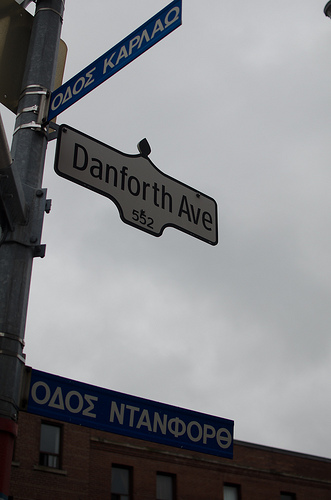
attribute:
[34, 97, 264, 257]
sign — letters , black 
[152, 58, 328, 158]
sky — blue, clear 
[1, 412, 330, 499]
building — brick, red , dark 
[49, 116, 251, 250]
sign — black , white 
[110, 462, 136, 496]
window — tall 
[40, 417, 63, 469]
window — tall 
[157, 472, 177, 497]
window — tall 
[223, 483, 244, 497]
window — tall 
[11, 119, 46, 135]
connector — metal  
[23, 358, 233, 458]
sign — blue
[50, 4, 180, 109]
letters — white 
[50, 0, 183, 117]
sign — blue 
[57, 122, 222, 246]
sign — black, letters , 552 , white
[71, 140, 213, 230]
letters — black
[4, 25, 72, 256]
pole — silver, tall 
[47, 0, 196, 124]
blue sign — Blue 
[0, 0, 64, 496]
pole — grey 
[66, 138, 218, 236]
sign — black and white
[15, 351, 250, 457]
sign — white , blue